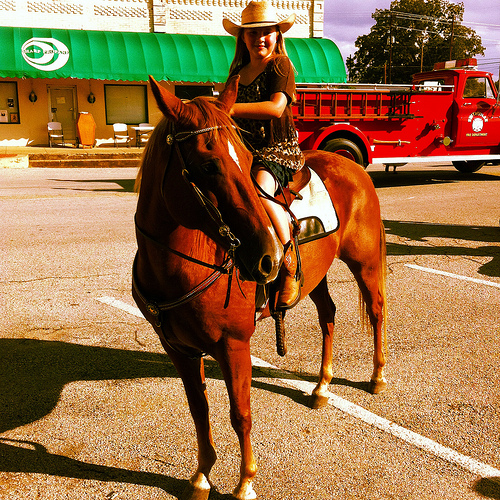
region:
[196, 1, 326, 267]
A young girl on a brown horse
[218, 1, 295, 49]
The girl is wearing a cowboy hat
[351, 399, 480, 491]
White lines designate parking spots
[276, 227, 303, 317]
The girls boots are brown and black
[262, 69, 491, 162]
An old firetruck behind the horse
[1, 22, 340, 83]
A green awning on a building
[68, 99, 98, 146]
This looks like a very small coffin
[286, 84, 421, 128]
Ladders on the side of the firetruck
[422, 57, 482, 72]
Lights on top of the firetruck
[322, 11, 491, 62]
It is sunny but there are clouds in the sky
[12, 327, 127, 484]
a shadow of the horse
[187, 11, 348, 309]
a girl sitting in the horse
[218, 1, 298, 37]
a hat on the girl's head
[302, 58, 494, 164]
a red color fire truck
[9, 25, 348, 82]
green color roof in front of the building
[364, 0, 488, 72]
tree with branches near the building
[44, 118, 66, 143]
chair in front of the building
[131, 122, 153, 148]
table infront of the building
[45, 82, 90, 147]
front door and chair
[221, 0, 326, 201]
a girl focusing on the camera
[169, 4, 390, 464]
little girl riding pony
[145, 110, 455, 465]
brown pony with white spot on head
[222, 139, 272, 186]
white diamond shaped spot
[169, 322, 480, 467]
white lines painted on asphalt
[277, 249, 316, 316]
brown boots on girl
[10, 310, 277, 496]
shadow of pony cast on parking lot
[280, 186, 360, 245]
white saddle on pony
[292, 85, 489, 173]
red fire truck in background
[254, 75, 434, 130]
ladder on side of truck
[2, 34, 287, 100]
green awning of building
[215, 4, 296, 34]
A hat in the photo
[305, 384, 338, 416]
Hoof in the photo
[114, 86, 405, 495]
A horse in the photo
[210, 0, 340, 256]
A lady riding a horse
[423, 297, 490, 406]
Paved floor in the photo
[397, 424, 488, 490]
White marks in the photo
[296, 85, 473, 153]
A truck in the photo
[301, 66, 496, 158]
A red truck in the photo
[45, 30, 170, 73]
Green roofing on the building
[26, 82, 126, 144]
A house in the photo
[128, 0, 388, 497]
a girl riding a horse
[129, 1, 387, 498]
a girl riding a brown horse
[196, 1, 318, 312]
a little girl wearing a cowboy hat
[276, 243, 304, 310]
boots the girl is wearing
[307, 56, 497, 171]
a fire truck in the background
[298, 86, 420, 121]
a ladder attached to the side of the fire truck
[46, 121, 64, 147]
a chair in the sidewalk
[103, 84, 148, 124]
a window of the building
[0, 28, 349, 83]
a green roof in the background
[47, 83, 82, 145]
an entry door of the building